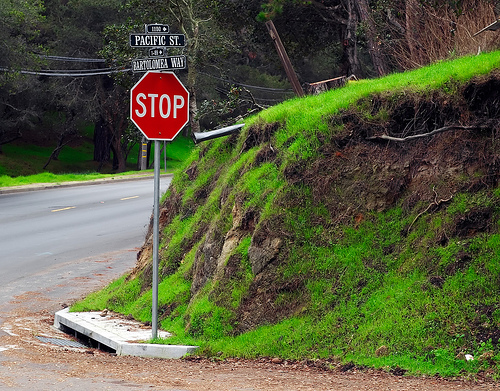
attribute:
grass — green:
[183, 278, 224, 343]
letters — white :
[147, 92, 157, 119]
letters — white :
[134, 90, 147, 116]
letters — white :
[158, 92, 171, 118]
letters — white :
[171, 92, 185, 117]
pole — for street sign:
[150, 145, 165, 346]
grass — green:
[68, 48, 498, 380]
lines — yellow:
[32, 198, 144, 217]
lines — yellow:
[12, 195, 95, 251]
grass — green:
[267, 97, 357, 157]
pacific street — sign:
[127, 31, 191, 47]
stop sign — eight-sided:
[128, 67, 195, 136]